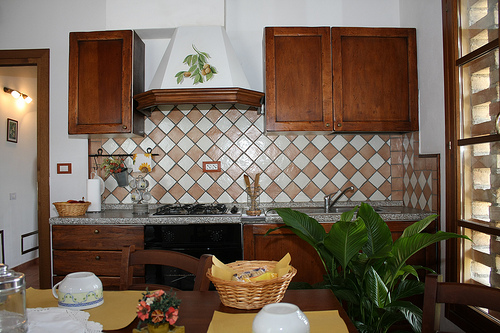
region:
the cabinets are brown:
[283, 61, 303, 91]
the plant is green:
[347, 244, 396, 297]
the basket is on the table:
[216, 282, 239, 318]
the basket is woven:
[230, 282, 266, 304]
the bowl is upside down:
[45, 269, 115, 308]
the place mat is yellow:
[105, 302, 127, 324]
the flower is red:
[103, 158, 127, 173]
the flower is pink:
[133, 298, 150, 322]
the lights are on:
[8, 84, 35, 108]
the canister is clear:
[5, 291, 25, 318]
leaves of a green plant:
[268, 201, 475, 331]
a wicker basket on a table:
[209, 257, 294, 309]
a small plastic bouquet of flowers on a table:
[136, 286, 179, 326]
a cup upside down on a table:
[51, 270, 106, 309]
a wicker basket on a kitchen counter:
[54, 198, 90, 215]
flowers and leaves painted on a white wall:
[173, 44, 218, 85]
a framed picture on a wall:
[6, 117, 19, 143]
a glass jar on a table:
[1, 263, 26, 331]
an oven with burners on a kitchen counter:
[146, 197, 243, 288]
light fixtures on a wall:
[3, 86, 30, 108]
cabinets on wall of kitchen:
[256, 28, 413, 135]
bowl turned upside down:
[250, 300, 317, 330]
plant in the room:
[272, 175, 445, 315]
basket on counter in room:
[57, 188, 94, 224]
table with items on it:
[2, 257, 352, 332]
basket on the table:
[221, 252, 296, 304]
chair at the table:
[116, 233, 211, 291]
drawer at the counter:
[51, 220, 146, 243]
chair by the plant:
[413, 265, 498, 329]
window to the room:
[454, 155, 494, 304]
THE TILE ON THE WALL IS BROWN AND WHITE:
[82, 95, 443, 211]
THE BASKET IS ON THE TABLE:
[201, 250, 293, 310]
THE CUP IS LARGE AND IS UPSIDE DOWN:
[40, 267, 110, 309]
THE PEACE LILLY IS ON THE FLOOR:
[260, 195, 475, 330]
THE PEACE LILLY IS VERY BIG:
[260, 192, 475, 330]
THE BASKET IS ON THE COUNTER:
[47, 192, 88, 222]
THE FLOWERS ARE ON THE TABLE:
[130, 287, 185, 330]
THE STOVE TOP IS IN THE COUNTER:
[137, 200, 242, 223]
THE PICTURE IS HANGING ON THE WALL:
[0, 117, 21, 147]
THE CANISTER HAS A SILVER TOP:
[0, 250, 33, 332]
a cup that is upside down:
[50, 270, 106, 307]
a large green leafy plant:
[264, 199, 451, 331]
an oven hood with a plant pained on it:
[138, 22, 263, 113]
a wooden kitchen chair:
[117, 242, 219, 291]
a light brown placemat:
[207, 306, 355, 331]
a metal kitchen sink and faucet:
[271, 185, 384, 216]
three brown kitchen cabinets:
[66, 22, 419, 136]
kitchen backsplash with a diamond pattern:
[86, 104, 443, 218]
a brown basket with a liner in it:
[206, 251, 300, 310]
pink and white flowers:
[134, 285, 179, 332]